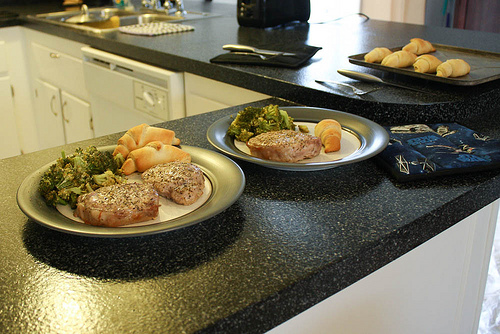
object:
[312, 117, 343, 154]
roll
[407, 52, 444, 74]
roll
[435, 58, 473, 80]
croissants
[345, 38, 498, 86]
pan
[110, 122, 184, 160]
crescent roll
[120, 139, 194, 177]
crescent roll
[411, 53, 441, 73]
pie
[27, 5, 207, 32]
sink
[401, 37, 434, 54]
pie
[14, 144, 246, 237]
plates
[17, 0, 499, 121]
counter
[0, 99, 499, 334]
counter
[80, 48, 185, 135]
dishwasher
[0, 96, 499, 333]
countertop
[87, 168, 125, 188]
vegetables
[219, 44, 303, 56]
knife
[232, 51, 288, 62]
fork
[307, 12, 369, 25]
cord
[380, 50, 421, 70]
pie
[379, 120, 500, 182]
mitt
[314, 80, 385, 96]
fork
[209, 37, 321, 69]
napkin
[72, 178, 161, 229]
meat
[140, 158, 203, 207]
meat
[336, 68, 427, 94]
knife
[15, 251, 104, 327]
glare